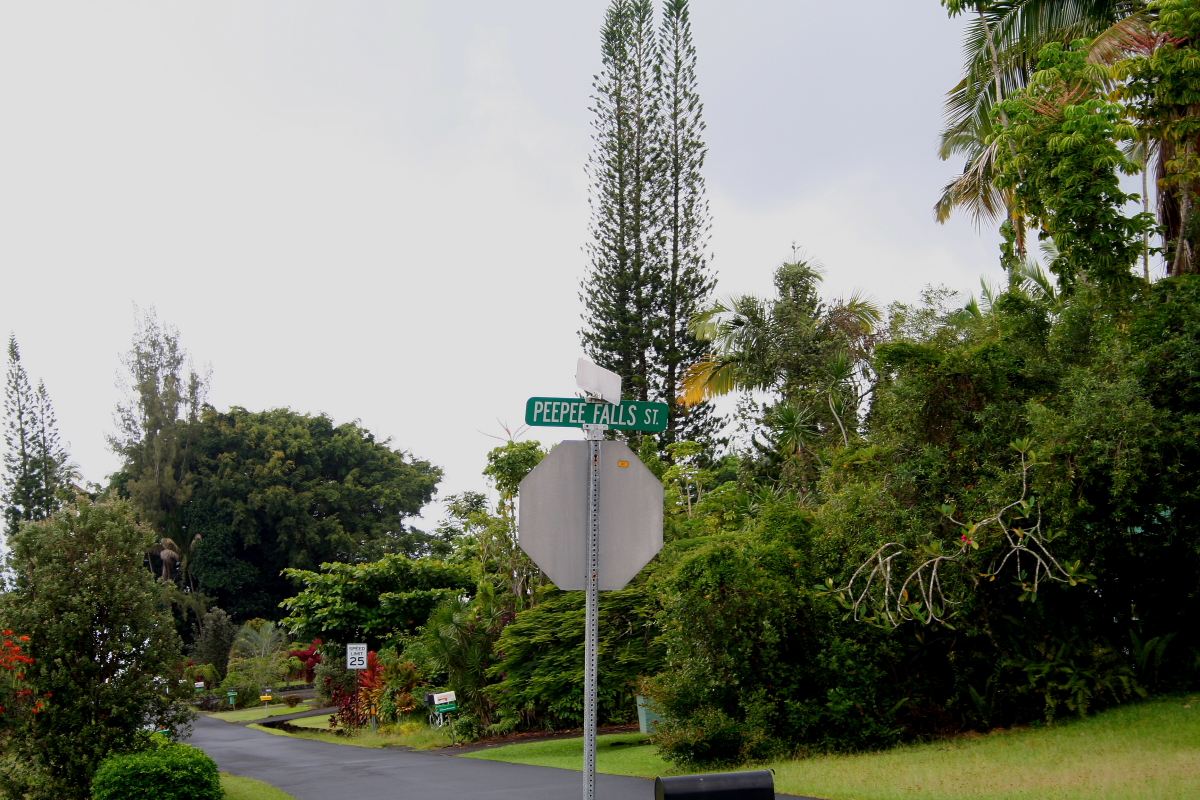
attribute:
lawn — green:
[362, 720, 643, 771]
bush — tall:
[0, 296, 60, 626]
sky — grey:
[14, 8, 968, 433]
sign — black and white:
[353, 632, 363, 678]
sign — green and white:
[521, 386, 673, 446]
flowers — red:
[364, 650, 394, 715]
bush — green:
[614, 538, 794, 769]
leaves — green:
[108, 411, 408, 560]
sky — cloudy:
[0, 75, 1176, 419]